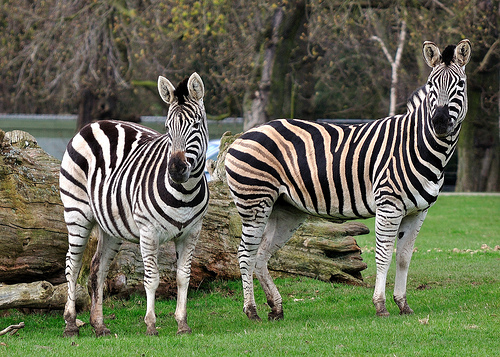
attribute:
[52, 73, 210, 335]
zebra — new, looking, black, white, in the picture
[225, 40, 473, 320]
zebra — young, black, white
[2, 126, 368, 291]
tree trunk — huge, grey, log, big, fallen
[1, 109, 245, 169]
water — colorless, in background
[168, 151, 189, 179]
nose — black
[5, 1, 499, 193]
forest — in background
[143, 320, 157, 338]
hoof — black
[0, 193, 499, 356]
grass — green, here, short, in the picture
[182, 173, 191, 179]
mouth — black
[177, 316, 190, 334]
hoof — grey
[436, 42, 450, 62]
fur — black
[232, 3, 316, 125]
tree — tall, in the picture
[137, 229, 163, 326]
limb — in the picture